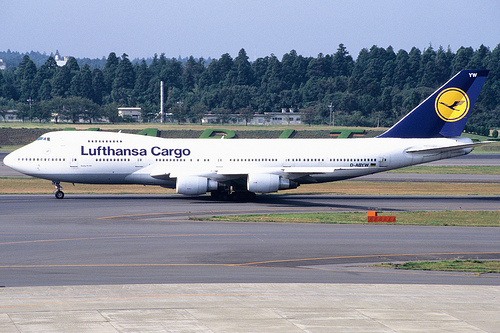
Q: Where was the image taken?
A: It was taken at the runway.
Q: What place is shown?
A: It is a runway.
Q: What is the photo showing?
A: It is showing a runway.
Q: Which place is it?
A: It is a runway.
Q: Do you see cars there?
A: No, there are no cars.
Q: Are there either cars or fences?
A: No, there are no cars or fences.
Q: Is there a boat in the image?
A: No, there are no boats.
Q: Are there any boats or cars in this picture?
A: No, there are no boats or cars.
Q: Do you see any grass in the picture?
A: Yes, there is grass.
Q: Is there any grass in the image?
A: Yes, there is grass.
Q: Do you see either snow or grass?
A: Yes, there is grass.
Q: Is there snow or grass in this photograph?
A: Yes, there is grass.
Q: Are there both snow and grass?
A: No, there is grass but no snow.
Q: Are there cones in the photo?
A: No, there are no cones.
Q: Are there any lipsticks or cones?
A: No, there are no cones or lipsticks.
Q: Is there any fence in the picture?
A: No, there are no fences.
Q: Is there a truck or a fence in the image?
A: No, there are no fences or trucks.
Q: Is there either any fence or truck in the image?
A: No, there are no fences or trucks.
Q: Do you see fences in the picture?
A: No, there are no fences.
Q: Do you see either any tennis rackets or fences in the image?
A: No, there are no fences or tennis rackets.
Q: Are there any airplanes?
A: Yes, there is an airplane.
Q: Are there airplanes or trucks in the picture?
A: Yes, there is an airplane.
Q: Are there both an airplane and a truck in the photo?
A: No, there is an airplane but no trucks.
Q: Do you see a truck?
A: No, there are no trucks.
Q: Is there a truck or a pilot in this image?
A: No, there are no trucks or pilots.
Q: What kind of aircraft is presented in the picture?
A: The aircraft is an airplane.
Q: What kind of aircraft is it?
A: The aircraft is an airplane.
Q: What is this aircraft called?
A: This is an airplane.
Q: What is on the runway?
A: The airplane is on the runway.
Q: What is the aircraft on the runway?
A: The aircraft is an airplane.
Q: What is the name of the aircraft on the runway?
A: The aircraft is an airplane.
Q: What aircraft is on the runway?
A: The aircraft is an airplane.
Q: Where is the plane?
A: The plane is on the runway.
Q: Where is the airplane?
A: The plane is on the runway.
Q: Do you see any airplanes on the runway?
A: Yes, there is an airplane on the runway.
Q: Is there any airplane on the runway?
A: Yes, there is an airplane on the runway.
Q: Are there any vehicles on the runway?
A: No, there is an airplane on the runway.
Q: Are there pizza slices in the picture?
A: No, there are no pizza slices.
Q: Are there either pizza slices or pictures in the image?
A: No, there are no pizza slices or pictures.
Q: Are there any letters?
A: Yes, there are letters.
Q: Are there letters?
A: Yes, there are letters.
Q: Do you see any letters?
A: Yes, there are letters.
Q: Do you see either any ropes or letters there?
A: Yes, there are letters.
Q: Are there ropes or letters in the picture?
A: Yes, there are letters.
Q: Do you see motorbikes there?
A: No, there are no motorbikes.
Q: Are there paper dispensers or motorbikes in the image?
A: No, there are no motorbikes or paper dispensers.